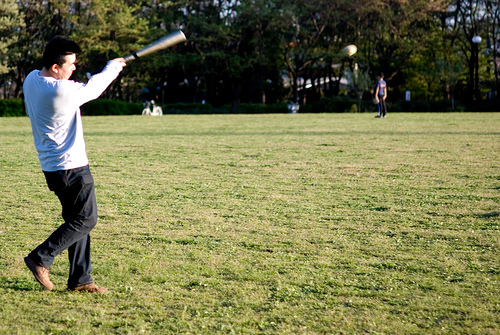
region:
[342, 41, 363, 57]
a small white baseball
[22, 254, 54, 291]
a man's brown shoe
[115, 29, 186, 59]
a gray and black baseball bat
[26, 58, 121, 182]
a man's long sleeve shirt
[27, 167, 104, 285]
a man's black pants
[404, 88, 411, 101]
a blue and white sign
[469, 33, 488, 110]
a tall lamp pole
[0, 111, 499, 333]
a large green field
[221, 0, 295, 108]
part of a tall green tree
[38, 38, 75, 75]
a man's short black hair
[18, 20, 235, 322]
Man holding a bat.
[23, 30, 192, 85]
Bat in the man's hand.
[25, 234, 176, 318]
Shoes on the man.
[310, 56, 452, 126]
People in the background.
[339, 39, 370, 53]
Ball in the air.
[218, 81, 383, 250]
Grass on the ground.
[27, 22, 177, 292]
Man in black pants.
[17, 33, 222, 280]
Man with a gray shirt.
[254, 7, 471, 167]
Trees in the distance.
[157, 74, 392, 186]
Bushes in the distance.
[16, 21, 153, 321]
man standing on the grass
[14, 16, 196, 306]
man holding a bat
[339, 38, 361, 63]
small white baseball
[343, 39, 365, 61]
baseball flying in the air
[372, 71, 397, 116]
man holding a baseball glove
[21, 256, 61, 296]
heel lifted of the ground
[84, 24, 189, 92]
silver bat is lifted up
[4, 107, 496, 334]
green grass on the ground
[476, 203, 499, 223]
small shadow on the ground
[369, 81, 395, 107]
arms are down by the sides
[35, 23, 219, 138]
man holding a bat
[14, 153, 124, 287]
the pants are black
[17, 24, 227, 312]
Person swinging a bat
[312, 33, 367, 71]
Regulation White Baseball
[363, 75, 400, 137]
Pitcher very far away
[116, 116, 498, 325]
Short Freshly Mowed Grass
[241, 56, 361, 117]
White House Behind The Tree Line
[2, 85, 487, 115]
Line of squared off bushes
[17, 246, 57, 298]
Brown Right Shoe Slanted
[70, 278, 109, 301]
Left brown shoe on grass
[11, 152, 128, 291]
Black Baggy Sports Pants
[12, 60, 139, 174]
Long Sleeved White Shirt